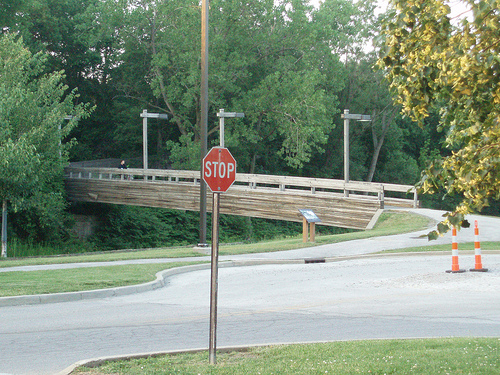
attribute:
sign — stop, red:
[199, 139, 242, 187]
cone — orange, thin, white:
[440, 215, 468, 278]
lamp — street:
[333, 94, 373, 199]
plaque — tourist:
[302, 207, 324, 234]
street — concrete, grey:
[276, 238, 406, 351]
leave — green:
[396, 41, 409, 55]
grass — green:
[119, 269, 133, 280]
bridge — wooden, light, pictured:
[213, 164, 377, 225]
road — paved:
[332, 224, 407, 296]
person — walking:
[95, 139, 153, 207]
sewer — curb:
[288, 251, 340, 280]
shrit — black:
[118, 161, 132, 173]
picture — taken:
[33, 14, 467, 349]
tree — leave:
[403, 90, 486, 175]